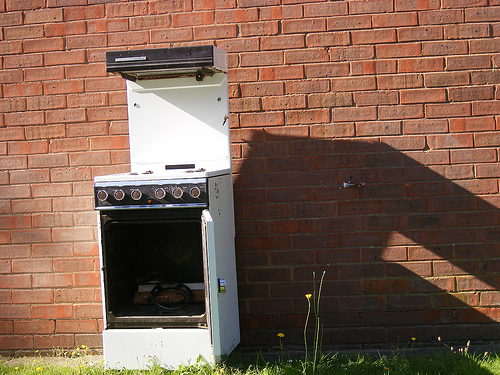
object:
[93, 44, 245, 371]
oven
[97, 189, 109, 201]
dials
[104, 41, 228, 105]
stand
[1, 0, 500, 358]
wall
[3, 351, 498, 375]
grass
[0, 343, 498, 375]
ground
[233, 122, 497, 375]
shadow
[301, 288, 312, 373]
dandelions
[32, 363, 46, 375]
flower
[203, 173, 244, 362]
side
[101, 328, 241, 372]
bottom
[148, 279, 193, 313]
cord